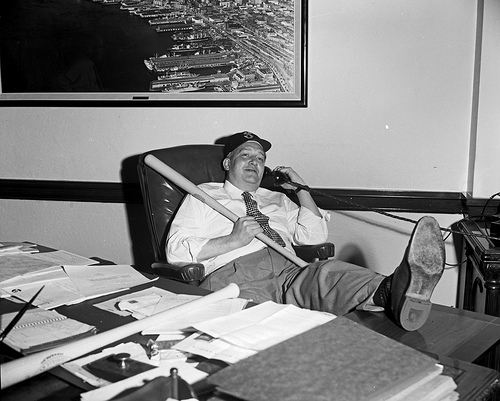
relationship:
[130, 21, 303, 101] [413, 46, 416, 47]
photo on wall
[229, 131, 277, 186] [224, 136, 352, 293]
face of man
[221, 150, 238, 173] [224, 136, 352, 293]
ear of man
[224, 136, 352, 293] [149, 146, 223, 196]
man holding bat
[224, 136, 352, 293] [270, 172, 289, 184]
man has phone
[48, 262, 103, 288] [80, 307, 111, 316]
papers on desk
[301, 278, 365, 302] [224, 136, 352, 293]
leg of man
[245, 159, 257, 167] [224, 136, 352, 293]
nose of man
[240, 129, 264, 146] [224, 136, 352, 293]
hat on man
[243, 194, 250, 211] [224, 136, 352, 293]
tie on man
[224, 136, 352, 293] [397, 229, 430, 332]
man wearing shoe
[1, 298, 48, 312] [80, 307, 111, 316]
pen on desk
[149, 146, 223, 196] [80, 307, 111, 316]
bat on desk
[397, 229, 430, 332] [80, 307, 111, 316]
shoe on desk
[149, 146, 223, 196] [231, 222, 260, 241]
bat in hand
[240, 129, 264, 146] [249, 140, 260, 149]
hat on head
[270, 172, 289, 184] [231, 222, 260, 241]
phone in hand